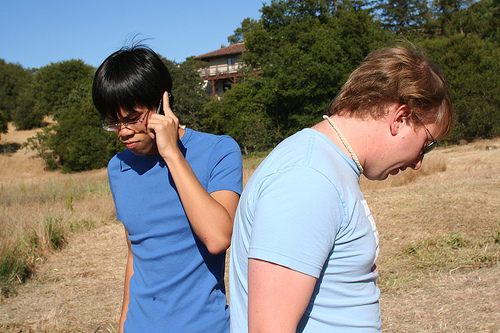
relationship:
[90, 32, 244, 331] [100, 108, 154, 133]
asian man wearing eyeglasses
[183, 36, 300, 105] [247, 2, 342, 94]
house surrounded by trees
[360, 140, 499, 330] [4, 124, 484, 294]
hillside in field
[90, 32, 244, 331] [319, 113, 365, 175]
asian man wearing necklace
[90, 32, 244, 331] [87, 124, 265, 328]
asian man wearing shirt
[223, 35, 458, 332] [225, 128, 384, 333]
boy wearing green shirt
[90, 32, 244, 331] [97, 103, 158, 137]
asian man wearing eyeglasses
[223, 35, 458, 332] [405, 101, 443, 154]
boy wearing glasses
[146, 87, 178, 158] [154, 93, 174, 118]
hand on cell phone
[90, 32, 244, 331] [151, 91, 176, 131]
asian man talking phone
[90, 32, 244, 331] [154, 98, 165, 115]
asian man talking cell phone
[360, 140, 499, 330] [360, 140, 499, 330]
hillside growing hillside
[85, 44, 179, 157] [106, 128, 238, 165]
mans head above shoulders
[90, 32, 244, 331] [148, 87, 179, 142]
asian man holding cellphone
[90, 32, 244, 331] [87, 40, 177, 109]
asian man with hair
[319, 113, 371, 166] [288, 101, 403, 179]
necklace around neck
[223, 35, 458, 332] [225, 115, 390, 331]
boy wears green shirt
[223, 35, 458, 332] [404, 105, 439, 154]
boy wearing glasses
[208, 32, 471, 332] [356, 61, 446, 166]
boy looking down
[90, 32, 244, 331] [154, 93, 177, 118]
asian man using cell phone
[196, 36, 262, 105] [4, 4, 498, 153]
house in background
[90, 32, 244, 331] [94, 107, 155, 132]
asian man wearing glasses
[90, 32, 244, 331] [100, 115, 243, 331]
asian man wearing shirt